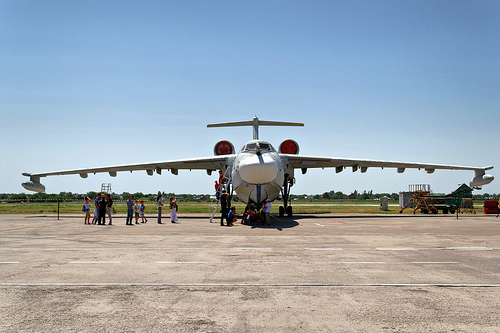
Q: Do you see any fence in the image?
A: No, there are no fences.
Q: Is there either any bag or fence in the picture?
A: No, there are no fences or bags.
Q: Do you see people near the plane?
A: Yes, there are people near the plane.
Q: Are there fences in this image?
A: No, there are no fences.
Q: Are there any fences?
A: No, there are no fences.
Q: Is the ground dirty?
A: Yes, the ground is dirty.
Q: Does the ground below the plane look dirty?
A: Yes, the ground is dirty.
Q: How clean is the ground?
A: The ground is dirty.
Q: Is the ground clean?
A: No, the ground is dirty.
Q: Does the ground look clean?
A: No, the ground is dirty.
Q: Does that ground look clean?
A: No, the ground is dirty.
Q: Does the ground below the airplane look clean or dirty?
A: The ground is dirty.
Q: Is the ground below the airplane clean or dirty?
A: The ground is dirty.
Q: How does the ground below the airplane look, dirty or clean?
A: The ground is dirty.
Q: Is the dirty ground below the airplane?
A: Yes, the ground is below the airplane.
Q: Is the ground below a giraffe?
A: No, the ground is below the airplane.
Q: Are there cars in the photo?
A: No, there are no cars.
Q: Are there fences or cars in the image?
A: No, there are no cars or fences.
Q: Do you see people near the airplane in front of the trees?
A: Yes, there are people near the plane.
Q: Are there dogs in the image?
A: No, there are no dogs.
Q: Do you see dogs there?
A: No, there are no dogs.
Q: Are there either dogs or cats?
A: No, there are no dogs or cats.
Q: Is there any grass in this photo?
A: Yes, there is grass.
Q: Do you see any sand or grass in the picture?
A: Yes, there is grass.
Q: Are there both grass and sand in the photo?
A: No, there is grass but no sand.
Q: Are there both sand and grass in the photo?
A: No, there is grass but no sand.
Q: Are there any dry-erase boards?
A: No, there are no dry-erase boards.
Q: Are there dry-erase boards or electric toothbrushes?
A: No, there are no dry-erase boards or electric toothbrushes.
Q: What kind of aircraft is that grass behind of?
A: The grass is behind the airplane.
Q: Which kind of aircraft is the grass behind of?
A: The grass is behind the airplane.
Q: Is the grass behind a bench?
A: No, the grass is behind the airplane.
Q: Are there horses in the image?
A: No, there are no horses.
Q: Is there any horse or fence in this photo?
A: No, there are no horses or fences.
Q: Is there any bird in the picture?
A: No, there are no birds.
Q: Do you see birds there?
A: No, there are no birds.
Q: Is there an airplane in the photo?
A: Yes, there is an airplane.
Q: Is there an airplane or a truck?
A: Yes, there is an airplane.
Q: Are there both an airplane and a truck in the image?
A: No, there is an airplane but no trucks.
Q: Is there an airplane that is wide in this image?
A: Yes, there is a wide airplane.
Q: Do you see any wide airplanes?
A: Yes, there is a wide airplane.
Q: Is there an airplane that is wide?
A: Yes, there is an airplane that is wide.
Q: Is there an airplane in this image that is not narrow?
A: Yes, there is a wide airplane.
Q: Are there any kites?
A: No, there are no kites.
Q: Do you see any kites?
A: No, there are no kites.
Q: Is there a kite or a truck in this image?
A: No, there are no kites or trucks.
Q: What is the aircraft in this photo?
A: The aircraft is an airplane.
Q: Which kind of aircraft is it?
A: The aircraft is an airplane.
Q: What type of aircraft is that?
A: This is an airplane.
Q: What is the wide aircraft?
A: The aircraft is an airplane.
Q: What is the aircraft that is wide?
A: The aircraft is an airplane.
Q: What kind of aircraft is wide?
A: The aircraft is an airplane.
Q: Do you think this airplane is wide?
A: Yes, the airplane is wide.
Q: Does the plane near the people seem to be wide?
A: Yes, the airplane is wide.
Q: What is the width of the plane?
A: The plane is wide.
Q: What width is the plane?
A: The plane is wide.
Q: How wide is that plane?
A: The plane is wide.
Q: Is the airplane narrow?
A: No, the airplane is wide.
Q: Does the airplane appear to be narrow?
A: No, the airplane is wide.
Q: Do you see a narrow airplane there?
A: No, there is an airplane but it is wide.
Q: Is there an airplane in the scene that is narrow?
A: No, there is an airplane but it is wide.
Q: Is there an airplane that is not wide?
A: No, there is an airplane but it is wide.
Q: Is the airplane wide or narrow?
A: The airplane is wide.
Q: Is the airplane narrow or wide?
A: The airplane is wide.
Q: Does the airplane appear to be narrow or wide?
A: The airplane is wide.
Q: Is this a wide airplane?
A: Yes, this is a wide airplane.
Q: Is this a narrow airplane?
A: No, this is a wide airplane.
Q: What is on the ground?
A: The plane is on the ground.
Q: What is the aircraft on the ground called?
A: The aircraft is an airplane.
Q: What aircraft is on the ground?
A: The aircraft is an airplane.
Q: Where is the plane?
A: The plane is on the ground.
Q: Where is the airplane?
A: The plane is on the ground.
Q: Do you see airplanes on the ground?
A: Yes, there is an airplane on the ground.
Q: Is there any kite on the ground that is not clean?
A: No, there is an airplane on the ground.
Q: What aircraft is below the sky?
A: The aircraft is an airplane.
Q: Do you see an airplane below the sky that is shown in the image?
A: Yes, there is an airplane below the sky.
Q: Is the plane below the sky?
A: Yes, the plane is below the sky.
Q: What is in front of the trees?
A: The airplane is in front of the trees.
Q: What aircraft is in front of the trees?
A: The aircraft is an airplane.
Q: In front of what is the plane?
A: The plane is in front of the trees.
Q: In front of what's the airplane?
A: The plane is in front of the trees.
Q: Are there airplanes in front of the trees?
A: Yes, there is an airplane in front of the trees.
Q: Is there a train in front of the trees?
A: No, there is an airplane in front of the trees.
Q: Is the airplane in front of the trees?
A: Yes, the airplane is in front of the trees.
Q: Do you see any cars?
A: No, there are no cars.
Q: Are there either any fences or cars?
A: No, there are no cars or fences.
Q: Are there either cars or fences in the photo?
A: No, there are no cars or fences.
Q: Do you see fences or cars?
A: No, there are no cars or fences.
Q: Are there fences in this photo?
A: No, there are no fences.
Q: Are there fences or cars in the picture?
A: No, there are no fences or cars.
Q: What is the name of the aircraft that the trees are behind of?
A: The aircraft is an airplane.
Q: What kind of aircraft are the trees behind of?
A: The trees are behind the plane.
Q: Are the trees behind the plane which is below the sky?
A: Yes, the trees are behind the plane.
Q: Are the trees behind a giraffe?
A: No, the trees are behind the plane.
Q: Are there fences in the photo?
A: No, there are no fences.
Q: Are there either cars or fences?
A: No, there are no fences or cars.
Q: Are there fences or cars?
A: No, there are no fences or cars.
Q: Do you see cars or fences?
A: No, there are no fences or cars.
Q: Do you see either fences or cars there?
A: No, there are no fences or cars.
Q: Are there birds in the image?
A: No, there are no birds.